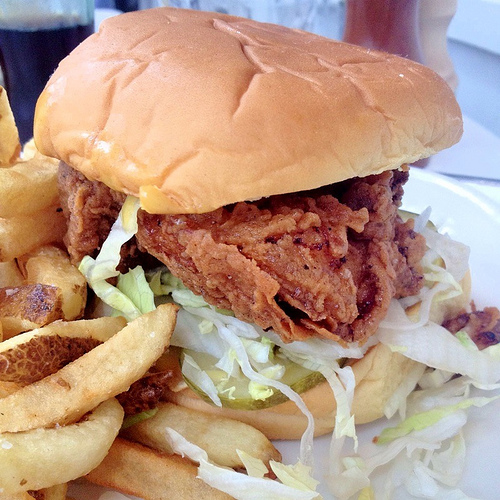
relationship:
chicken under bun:
[52, 173, 427, 302] [52, 12, 460, 180]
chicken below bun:
[52, 173, 427, 302] [52, 12, 460, 180]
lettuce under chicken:
[72, 199, 467, 402] [52, 173, 427, 302]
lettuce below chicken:
[72, 199, 467, 402] [52, 173, 427, 302]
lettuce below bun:
[72, 199, 467, 402] [52, 12, 460, 180]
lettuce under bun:
[72, 199, 467, 402] [52, 12, 460, 180]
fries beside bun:
[2, 102, 221, 498] [52, 12, 460, 180]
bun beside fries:
[52, 12, 460, 180] [2, 102, 221, 498]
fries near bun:
[2, 102, 221, 498] [52, 12, 460, 180]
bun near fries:
[52, 12, 460, 180] [2, 102, 221, 498]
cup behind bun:
[2, 5, 89, 153] [52, 12, 460, 180]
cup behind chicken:
[2, 5, 89, 153] [52, 173, 427, 302]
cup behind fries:
[2, 5, 89, 153] [2, 102, 221, 498]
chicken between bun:
[52, 173, 427, 302] [31, 8, 461, 222]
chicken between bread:
[52, 173, 427, 302] [190, 239, 484, 439]